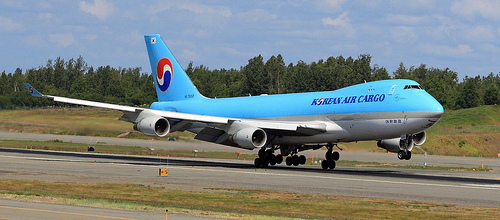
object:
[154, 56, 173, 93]
airline logo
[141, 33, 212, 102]
tail fin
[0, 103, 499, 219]
grass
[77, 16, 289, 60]
cloudy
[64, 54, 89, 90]
tree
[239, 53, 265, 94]
tree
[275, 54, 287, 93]
tree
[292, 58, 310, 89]
tree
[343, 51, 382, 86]
tree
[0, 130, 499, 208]
runway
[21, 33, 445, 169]
airplane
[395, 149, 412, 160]
wheel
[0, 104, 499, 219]
ground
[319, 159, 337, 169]
gear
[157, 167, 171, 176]
sign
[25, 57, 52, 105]
tree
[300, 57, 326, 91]
tree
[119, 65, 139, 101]
tree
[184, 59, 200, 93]
tree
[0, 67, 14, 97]
tree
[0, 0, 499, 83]
skies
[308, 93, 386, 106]
lettering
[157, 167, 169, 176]
orange light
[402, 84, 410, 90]
window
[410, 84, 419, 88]
window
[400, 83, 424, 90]
cockpit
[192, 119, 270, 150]
engines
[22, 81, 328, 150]
wing